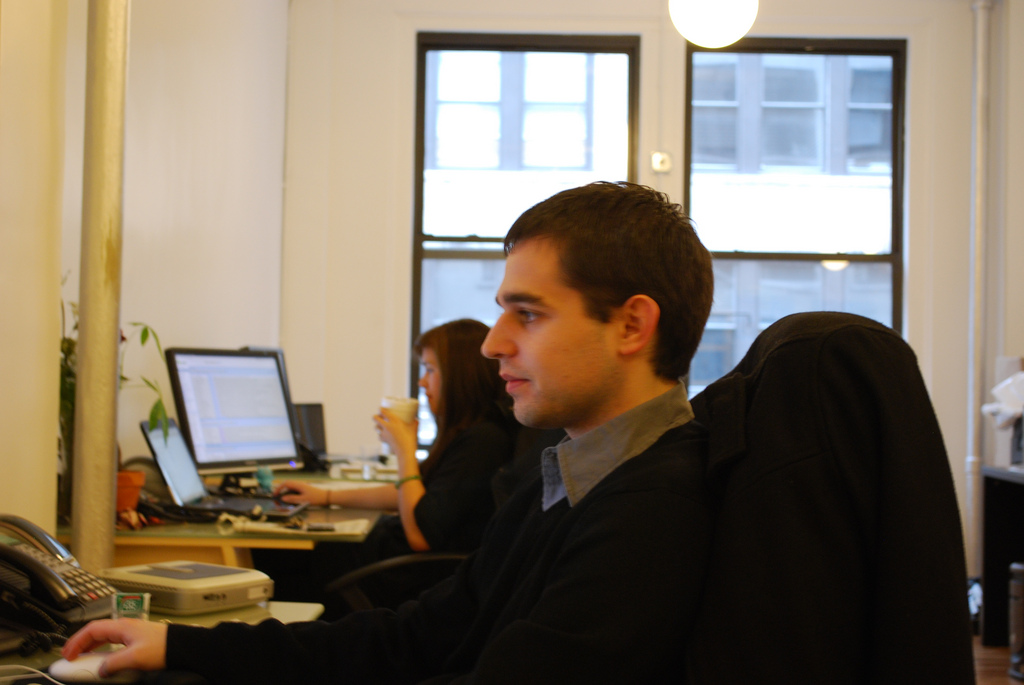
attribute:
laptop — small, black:
[135, 404, 307, 529]